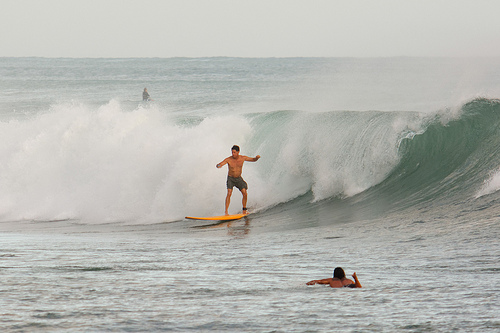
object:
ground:
[447, 161, 462, 171]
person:
[141, 87, 151, 100]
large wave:
[0, 94, 499, 228]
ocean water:
[0, 56, 499, 332]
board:
[185, 211, 248, 222]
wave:
[0, 100, 499, 226]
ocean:
[0, 54, 497, 331]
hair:
[333, 266, 346, 278]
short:
[227, 176, 249, 190]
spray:
[0, 94, 216, 224]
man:
[306, 266, 363, 288]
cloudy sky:
[1, 0, 498, 59]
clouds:
[0, 0, 499, 63]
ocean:
[328, 113, 483, 235]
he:
[216, 144, 263, 216]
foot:
[352, 272, 357, 278]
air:
[0, 1, 499, 333]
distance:
[0, 57, 499, 129]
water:
[0, 56, 499, 332]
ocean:
[8, 56, 480, 315]